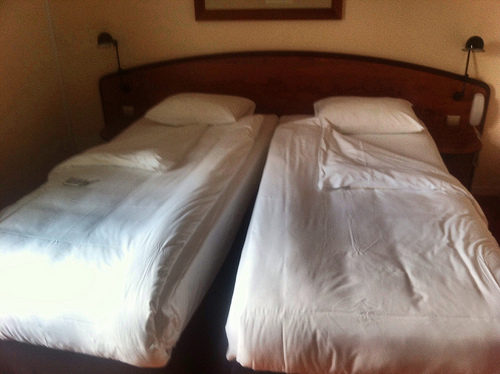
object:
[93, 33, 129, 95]
lamp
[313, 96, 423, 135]
pillow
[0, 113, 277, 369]
bed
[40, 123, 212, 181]
comforter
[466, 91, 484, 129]
phone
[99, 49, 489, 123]
headboard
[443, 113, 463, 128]
lightswitch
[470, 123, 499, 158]
cord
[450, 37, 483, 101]
lamps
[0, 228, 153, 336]
sun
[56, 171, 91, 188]
object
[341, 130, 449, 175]
sheet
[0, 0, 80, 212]
wall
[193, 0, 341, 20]
artwork